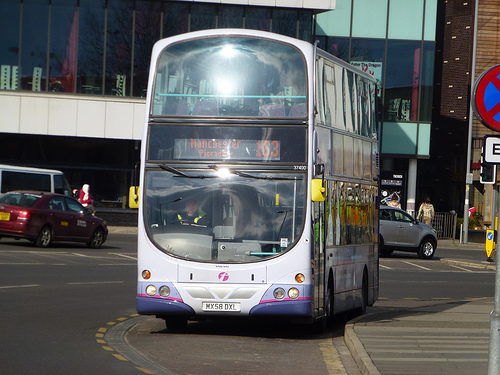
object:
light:
[145, 283, 157, 297]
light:
[158, 284, 172, 296]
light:
[287, 287, 299, 300]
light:
[272, 286, 286, 299]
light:
[294, 270, 304, 285]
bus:
[134, 28, 383, 329]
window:
[75, 0, 108, 95]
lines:
[1, 279, 44, 291]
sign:
[473, 65, 497, 132]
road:
[4, 225, 499, 374]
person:
[414, 197, 432, 225]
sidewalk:
[438, 237, 497, 263]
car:
[376, 204, 437, 259]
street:
[0, 230, 500, 374]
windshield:
[140, 160, 306, 263]